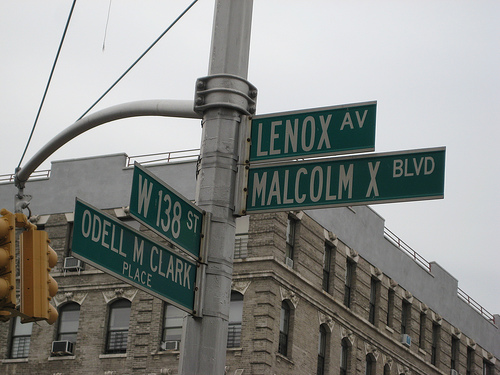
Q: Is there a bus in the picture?
A: No, there are no buses.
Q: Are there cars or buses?
A: No, there are no buses or cars.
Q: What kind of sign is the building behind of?
A: The building is behind the street sign.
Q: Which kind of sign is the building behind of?
A: The building is behind the street sign.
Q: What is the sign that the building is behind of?
A: The sign is a street sign.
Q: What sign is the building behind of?
A: The building is behind the street sign.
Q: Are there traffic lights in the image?
A: Yes, there is a traffic light.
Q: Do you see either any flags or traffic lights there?
A: Yes, there is a traffic light.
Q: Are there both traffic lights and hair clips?
A: No, there is a traffic light but no hair clips.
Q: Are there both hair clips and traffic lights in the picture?
A: No, there is a traffic light but no hair clips.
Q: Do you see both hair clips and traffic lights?
A: No, there is a traffic light but no hair clips.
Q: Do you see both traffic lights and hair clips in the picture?
A: No, there is a traffic light but no hair clips.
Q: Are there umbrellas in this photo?
A: No, there are no umbrellas.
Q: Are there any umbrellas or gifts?
A: No, there are no umbrellas or gifts.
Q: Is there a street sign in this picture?
A: Yes, there is a street sign.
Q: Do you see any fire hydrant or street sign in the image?
A: Yes, there is a street sign.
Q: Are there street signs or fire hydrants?
A: Yes, there is a street sign.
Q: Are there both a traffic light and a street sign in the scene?
A: Yes, there are both a street sign and a traffic light.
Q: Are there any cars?
A: No, there are no cars.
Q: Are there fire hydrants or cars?
A: No, there are no cars or fire hydrants.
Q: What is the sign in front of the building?
A: The sign is a street sign.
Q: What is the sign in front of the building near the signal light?
A: The sign is a street sign.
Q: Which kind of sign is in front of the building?
A: The sign is a street sign.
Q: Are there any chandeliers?
A: No, there are no chandeliers.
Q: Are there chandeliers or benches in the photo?
A: No, there are no chandeliers or benches.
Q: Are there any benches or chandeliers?
A: No, there are no chandeliers or benches.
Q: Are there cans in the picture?
A: No, there are no cans.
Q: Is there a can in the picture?
A: No, there are no cans.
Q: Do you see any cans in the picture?
A: No, there are no cans.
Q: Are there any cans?
A: No, there are no cans.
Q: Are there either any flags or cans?
A: No, there are no cans or flags.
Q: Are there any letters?
A: Yes, there are letters.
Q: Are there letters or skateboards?
A: Yes, there are letters.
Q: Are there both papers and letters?
A: No, there are letters but no papers.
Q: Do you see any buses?
A: No, there are no buses.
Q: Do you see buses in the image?
A: No, there are no buses.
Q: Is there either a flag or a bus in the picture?
A: No, there are no buses or flags.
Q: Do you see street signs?
A: Yes, there is a street sign.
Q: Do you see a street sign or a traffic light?
A: Yes, there is a street sign.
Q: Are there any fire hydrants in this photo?
A: No, there are no fire hydrants.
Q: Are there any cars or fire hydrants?
A: No, there are no fire hydrants or cars.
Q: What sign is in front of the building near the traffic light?
A: The sign is a street sign.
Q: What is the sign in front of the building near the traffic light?
A: The sign is a street sign.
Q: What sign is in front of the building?
A: The sign is a street sign.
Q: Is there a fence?
A: Yes, there is a fence.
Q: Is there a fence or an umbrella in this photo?
A: Yes, there is a fence.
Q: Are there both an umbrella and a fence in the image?
A: No, there is a fence but no umbrellas.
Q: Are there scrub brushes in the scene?
A: No, there are no scrub brushes.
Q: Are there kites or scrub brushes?
A: No, there are no scrub brushes or kites.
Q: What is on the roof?
A: The fence is on the roof.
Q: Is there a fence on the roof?
A: Yes, there is a fence on the roof.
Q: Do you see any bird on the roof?
A: No, there is a fence on the roof.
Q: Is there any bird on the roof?
A: No, there is a fence on the roof.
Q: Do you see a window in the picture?
A: Yes, there is a window.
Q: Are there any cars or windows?
A: Yes, there is a window.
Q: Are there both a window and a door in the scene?
A: No, there is a window but no doors.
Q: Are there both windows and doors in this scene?
A: No, there is a window but no doors.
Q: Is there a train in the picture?
A: No, there are no trains.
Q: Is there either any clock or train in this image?
A: No, there are no trains or clocks.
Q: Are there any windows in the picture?
A: Yes, there is a window.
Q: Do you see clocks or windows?
A: Yes, there is a window.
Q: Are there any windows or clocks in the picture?
A: Yes, there is a window.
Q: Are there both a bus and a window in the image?
A: No, there is a window but no buses.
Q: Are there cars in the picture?
A: No, there are no cars.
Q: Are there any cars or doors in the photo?
A: No, there are no cars or doors.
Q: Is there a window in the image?
A: Yes, there is a window.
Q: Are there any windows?
A: Yes, there is a window.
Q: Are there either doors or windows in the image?
A: Yes, there is a window.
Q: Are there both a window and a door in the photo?
A: No, there is a window but no doors.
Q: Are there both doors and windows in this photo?
A: No, there is a window but no doors.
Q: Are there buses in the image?
A: No, there are no buses.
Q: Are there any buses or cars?
A: No, there are no buses or cars.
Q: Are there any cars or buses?
A: No, there are no buses or cars.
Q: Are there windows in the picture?
A: Yes, there is a window.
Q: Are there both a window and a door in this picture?
A: No, there is a window but no doors.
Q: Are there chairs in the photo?
A: No, there are no chairs.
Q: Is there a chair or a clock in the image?
A: No, there are no chairs or clocks.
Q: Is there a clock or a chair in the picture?
A: No, there are no chairs or clocks.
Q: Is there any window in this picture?
A: Yes, there is a window.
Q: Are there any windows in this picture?
A: Yes, there is a window.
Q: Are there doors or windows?
A: Yes, there is a window.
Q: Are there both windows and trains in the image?
A: No, there is a window but no trains.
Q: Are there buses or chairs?
A: No, there are no buses or chairs.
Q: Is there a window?
A: Yes, there is a window.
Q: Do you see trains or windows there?
A: Yes, there is a window.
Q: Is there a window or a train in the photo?
A: Yes, there is a window.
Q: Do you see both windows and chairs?
A: No, there is a window but no chairs.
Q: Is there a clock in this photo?
A: No, there are no clocks.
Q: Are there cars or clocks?
A: No, there are no clocks or cars.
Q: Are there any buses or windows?
A: Yes, there is a window.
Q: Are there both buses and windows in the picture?
A: No, there is a window but no buses.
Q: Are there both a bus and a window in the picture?
A: No, there is a window but no buses.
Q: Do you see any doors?
A: No, there are no doors.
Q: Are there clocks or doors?
A: No, there are no doors or clocks.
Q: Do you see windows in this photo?
A: Yes, there is a window.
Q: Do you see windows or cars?
A: Yes, there is a window.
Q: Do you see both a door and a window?
A: No, there is a window but no doors.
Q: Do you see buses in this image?
A: No, there are no buses.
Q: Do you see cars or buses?
A: No, there are no buses or cars.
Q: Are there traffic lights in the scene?
A: Yes, there is a traffic light.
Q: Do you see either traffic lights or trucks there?
A: Yes, there is a traffic light.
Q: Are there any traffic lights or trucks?
A: Yes, there is a traffic light.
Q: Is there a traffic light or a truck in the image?
A: Yes, there is a traffic light.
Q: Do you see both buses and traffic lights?
A: No, there is a traffic light but no buses.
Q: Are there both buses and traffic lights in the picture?
A: No, there is a traffic light but no buses.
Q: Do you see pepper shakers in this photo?
A: No, there are no pepper shakers.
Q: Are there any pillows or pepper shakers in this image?
A: No, there are no pepper shakers or pillows.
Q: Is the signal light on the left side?
A: Yes, the signal light is on the left of the image.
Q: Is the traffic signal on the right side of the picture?
A: No, the traffic signal is on the left of the image.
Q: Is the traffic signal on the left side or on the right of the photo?
A: The traffic signal is on the left of the image.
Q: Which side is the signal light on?
A: The signal light is on the left of the image.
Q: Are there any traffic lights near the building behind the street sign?
A: Yes, there is a traffic light near the building.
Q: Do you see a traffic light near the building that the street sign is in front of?
A: Yes, there is a traffic light near the building.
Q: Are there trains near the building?
A: No, there is a traffic light near the building.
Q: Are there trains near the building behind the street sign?
A: No, there is a traffic light near the building.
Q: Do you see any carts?
A: No, there are no carts.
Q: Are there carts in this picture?
A: No, there are no carts.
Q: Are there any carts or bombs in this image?
A: No, there are no carts or bombs.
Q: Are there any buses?
A: No, there are no buses.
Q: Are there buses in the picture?
A: No, there are no buses.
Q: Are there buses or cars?
A: No, there are no buses or cars.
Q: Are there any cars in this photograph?
A: No, there are no cars.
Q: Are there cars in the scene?
A: No, there are no cars.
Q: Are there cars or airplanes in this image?
A: No, there are no cars or airplanes.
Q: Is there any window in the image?
A: Yes, there is a window.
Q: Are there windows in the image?
A: Yes, there is a window.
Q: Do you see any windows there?
A: Yes, there is a window.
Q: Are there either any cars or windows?
A: Yes, there is a window.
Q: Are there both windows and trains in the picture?
A: No, there is a window but no trains.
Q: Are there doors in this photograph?
A: No, there are no doors.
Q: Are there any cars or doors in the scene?
A: No, there are no doors or cars.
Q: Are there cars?
A: No, there are no cars.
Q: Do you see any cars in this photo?
A: No, there are no cars.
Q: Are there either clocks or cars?
A: No, there are no cars or clocks.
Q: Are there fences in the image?
A: Yes, there is a fence.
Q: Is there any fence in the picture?
A: Yes, there is a fence.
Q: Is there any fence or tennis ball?
A: Yes, there is a fence.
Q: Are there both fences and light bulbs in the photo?
A: No, there is a fence but no light bulbs.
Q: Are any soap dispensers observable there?
A: No, there are no soap dispensers.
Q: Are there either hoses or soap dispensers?
A: No, there are no soap dispensers or hoses.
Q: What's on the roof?
A: The fence is on the roof.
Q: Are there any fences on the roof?
A: Yes, there is a fence on the roof.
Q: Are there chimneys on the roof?
A: No, there is a fence on the roof.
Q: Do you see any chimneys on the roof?
A: No, there is a fence on the roof.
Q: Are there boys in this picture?
A: No, there are no boys.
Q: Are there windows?
A: Yes, there is a window.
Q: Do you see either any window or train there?
A: Yes, there is a window.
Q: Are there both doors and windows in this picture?
A: No, there is a window but no doors.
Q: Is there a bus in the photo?
A: No, there are no buses.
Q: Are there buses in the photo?
A: No, there are no buses.